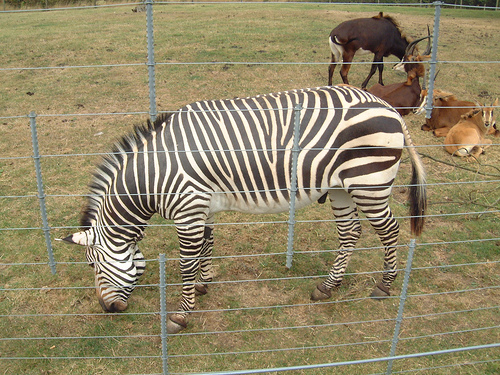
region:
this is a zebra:
[40, 67, 462, 339]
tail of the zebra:
[403, 115, 437, 232]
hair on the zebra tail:
[408, 145, 447, 239]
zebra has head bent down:
[34, 122, 170, 327]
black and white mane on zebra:
[37, 105, 179, 247]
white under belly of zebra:
[203, 182, 333, 229]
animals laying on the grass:
[352, 47, 497, 139]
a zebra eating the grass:
[61, 90, 421, 312]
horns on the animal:
[401, 30, 426, 45]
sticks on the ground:
[436, 151, 491, 211]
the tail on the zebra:
[390, 115, 420, 230]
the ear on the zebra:
[58, 234, 98, 243]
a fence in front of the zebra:
[0, 47, 495, 354]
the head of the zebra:
[70, 210, 147, 312]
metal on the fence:
[152, 254, 171, 374]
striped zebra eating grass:
[58, 84, 440, 331]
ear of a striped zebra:
[52, 224, 95, 250]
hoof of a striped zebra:
[161, 310, 190, 337]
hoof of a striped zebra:
[189, 279, 211, 297]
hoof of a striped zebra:
[306, 279, 333, 304]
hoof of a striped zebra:
[366, 280, 392, 301]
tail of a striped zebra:
[400, 117, 432, 244]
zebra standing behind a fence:
[50, 84, 446, 346]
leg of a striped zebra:
[154, 191, 217, 338]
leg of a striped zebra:
[307, 181, 362, 301]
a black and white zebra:
[58, 85, 435, 339]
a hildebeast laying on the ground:
[445, 94, 499, 161]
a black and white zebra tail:
[393, 102, 435, 235]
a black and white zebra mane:
[67, 97, 177, 267]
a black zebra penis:
[317, 190, 332, 210]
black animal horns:
[401, 24, 437, 62]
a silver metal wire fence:
[5, 11, 495, 368]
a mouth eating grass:
[376, 41, 424, 124]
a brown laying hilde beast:
[364, 50, 431, 118]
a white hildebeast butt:
[326, 27, 346, 67]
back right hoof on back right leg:
[292, 250, 368, 317]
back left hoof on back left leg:
[346, 244, 418, 316]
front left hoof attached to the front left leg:
[149, 272, 228, 342]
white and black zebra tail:
[390, 103, 454, 264]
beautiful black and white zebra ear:
[37, 212, 114, 267]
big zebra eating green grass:
[38, 89, 438, 373]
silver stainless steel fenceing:
[148, 243, 439, 366]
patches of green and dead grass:
[25, 35, 109, 135]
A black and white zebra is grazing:
[47, 75, 432, 335]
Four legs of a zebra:
[160, 190, 410, 337]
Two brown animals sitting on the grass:
[420, 75, 496, 165]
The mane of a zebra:
[70, 102, 177, 232]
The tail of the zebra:
[400, 116, 435, 241]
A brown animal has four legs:
[315, 2, 430, 89]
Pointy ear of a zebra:
[46, 218, 101, 251]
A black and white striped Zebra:
[39, 74, 454, 344]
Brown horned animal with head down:
[305, 11, 442, 86]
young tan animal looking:
[455, 85, 491, 165]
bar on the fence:
[20, 117, 70, 292]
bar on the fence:
[105, 5, 170, 131]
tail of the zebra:
[385, 102, 436, 242]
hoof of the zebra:
[300, 275, 336, 303]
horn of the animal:
[402, 33, 429, 58]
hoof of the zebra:
[165, 316, 195, 344]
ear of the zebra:
[57, 228, 94, 249]